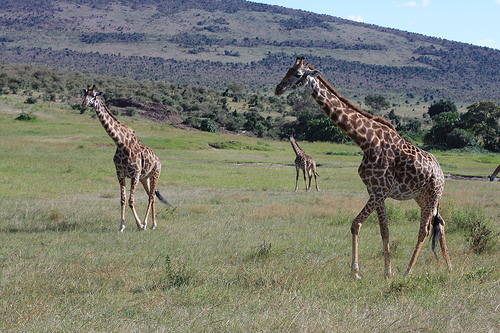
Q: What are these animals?
A: Giraffes.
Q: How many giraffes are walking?
A: Three.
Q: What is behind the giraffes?
A: A mountain.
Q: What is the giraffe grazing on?
A: Grass.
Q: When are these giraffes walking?
A: Day time.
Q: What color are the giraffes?
A: Brown and white.